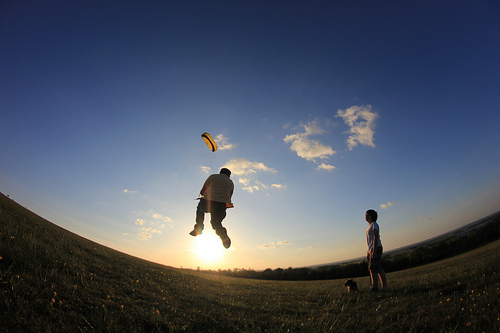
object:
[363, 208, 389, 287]
woman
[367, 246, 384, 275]
capris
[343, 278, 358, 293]
dog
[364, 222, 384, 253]
t-shirt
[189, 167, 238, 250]
man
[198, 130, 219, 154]
kite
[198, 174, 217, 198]
harness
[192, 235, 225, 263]
sun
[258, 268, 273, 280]
tree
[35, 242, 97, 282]
field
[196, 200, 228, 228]
jeans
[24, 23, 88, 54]
sky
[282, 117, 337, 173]
clouds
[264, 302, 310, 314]
grass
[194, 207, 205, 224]
leg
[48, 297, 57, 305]
flowers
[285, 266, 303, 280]
trees